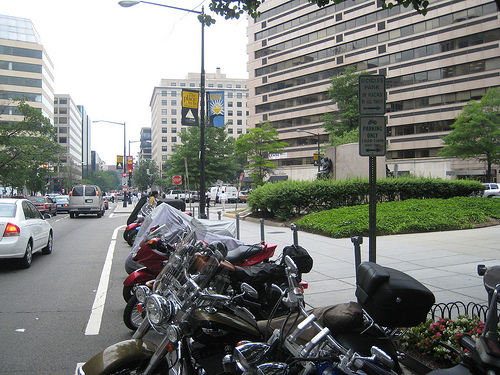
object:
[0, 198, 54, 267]
car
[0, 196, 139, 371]
road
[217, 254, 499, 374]
bikes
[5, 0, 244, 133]
sky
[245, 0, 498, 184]
building